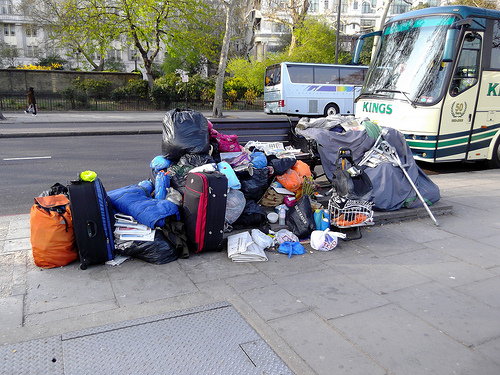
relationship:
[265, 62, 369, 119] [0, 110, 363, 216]
bus parked on road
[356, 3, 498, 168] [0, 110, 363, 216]
bus parked on road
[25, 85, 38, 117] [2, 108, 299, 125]
person walking on sidewalk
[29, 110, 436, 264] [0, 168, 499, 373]
pile on sidewalk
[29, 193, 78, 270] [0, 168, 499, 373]
bag on sidewalk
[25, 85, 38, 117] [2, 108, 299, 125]
person on sidewalk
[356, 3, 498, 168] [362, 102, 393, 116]
bus has writing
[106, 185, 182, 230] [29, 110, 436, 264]
coat in pile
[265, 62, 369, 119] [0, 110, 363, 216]
bus on road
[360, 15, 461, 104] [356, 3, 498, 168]
windshield of bus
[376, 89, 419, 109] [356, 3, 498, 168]
wiper on bus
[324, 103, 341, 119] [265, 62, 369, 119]
wheel on bus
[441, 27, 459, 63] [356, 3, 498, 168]
side view mirror on bus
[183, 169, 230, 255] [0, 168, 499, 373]
suitcase on sidewalk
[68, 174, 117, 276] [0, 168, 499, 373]
suitcase on sidewalk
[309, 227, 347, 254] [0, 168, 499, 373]
bag on sidewalk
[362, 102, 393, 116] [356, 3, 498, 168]
writing on front of bus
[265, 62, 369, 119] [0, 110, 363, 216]
bus parked on side of road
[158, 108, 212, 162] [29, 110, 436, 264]
trash bag on top of pile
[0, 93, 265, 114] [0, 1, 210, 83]
fence in front of building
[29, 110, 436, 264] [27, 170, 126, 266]
pile of stuf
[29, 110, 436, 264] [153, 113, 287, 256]
pile of stuf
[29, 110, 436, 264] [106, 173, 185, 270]
pile of stuf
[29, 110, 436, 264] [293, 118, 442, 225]
pile of stuff